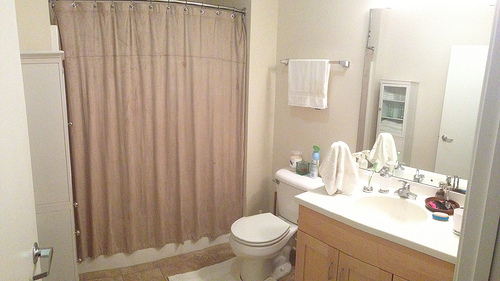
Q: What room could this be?
A: It is a bathroom.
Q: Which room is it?
A: It is a bathroom.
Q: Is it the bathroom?
A: Yes, it is the bathroom.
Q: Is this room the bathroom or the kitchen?
A: It is the bathroom.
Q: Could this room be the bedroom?
A: No, it is the bathroom.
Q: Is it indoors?
A: Yes, it is indoors.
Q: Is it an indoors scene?
A: Yes, it is indoors.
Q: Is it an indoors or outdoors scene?
A: It is indoors.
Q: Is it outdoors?
A: No, it is indoors.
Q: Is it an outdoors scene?
A: No, it is indoors.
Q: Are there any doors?
A: Yes, there is a door.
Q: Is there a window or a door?
A: Yes, there is a door.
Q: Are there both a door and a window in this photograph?
A: No, there is a door but no windows.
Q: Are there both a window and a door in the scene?
A: No, there is a door but no windows.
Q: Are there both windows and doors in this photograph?
A: No, there is a door but no windows.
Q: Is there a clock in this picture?
A: No, there are no clocks.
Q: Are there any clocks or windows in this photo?
A: No, there are no clocks or windows.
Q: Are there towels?
A: Yes, there is a towel.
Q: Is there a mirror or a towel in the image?
A: Yes, there is a towel.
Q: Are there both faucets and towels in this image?
A: Yes, there are both a towel and a faucet.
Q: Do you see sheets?
A: No, there are no sheets.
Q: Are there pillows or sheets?
A: No, there are no sheets or pillows.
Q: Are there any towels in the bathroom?
A: Yes, there is a towel in the bathroom.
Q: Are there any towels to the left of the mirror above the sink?
A: Yes, there is a towel to the left of the mirror.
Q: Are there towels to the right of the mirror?
A: No, the towel is to the left of the mirror.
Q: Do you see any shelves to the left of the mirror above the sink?
A: No, there is a towel to the left of the mirror.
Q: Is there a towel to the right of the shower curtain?
A: Yes, there is a towel to the right of the shower curtain.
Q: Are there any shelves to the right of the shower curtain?
A: No, there is a towel to the right of the shower curtain.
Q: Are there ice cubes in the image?
A: No, there are no ice cubes.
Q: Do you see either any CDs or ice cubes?
A: No, there are no ice cubes or cds.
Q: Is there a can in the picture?
A: Yes, there is a can.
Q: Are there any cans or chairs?
A: Yes, there is a can.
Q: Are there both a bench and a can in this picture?
A: No, there is a can but no benches.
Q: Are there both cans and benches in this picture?
A: No, there is a can but no benches.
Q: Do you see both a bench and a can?
A: No, there is a can but no benches.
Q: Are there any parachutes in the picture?
A: No, there are no parachutes.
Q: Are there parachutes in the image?
A: No, there are no parachutes.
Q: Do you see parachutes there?
A: No, there are no parachutes.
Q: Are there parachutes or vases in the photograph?
A: No, there are no parachutes or vases.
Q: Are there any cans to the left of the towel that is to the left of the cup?
A: Yes, there is a can to the left of the towel.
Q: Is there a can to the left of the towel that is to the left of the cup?
A: Yes, there is a can to the left of the towel.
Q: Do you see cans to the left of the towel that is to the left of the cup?
A: Yes, there is a can to the left of the towel.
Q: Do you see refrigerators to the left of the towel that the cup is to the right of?
A: No, there is a can to the left of the towel.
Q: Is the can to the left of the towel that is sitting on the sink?
A: Yes, the can is to the left of the towel.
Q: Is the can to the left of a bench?
A: No, the can is to the left of the towel.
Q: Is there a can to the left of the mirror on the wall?
A: Yes, there is a can to the left of the mirror.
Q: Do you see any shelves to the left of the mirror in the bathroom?
A: No, there is a can to the left of the mirror.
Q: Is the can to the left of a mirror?
A: Yes, the can is to the left of a mirror.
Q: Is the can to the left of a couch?
A: No, the can is to the left of a mirror.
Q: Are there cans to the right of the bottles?
A: Yes, there is a can to the right of the bottles.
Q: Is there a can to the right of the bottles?
A: Yes, there is a can to the right of the bottles.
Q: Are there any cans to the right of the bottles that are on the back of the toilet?
A: Yes, there is a can to the right of the bottles.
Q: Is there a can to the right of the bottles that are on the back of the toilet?
A: Yes, there is a can to the right of the bottles.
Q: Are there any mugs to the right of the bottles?
A: No, there is a can to the right of the bottles.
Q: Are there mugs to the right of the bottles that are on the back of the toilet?
A: No, there is a can to the right of the bottles.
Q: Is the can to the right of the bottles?
A: Yes, the can is to the right of the bottles.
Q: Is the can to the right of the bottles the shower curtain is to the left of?
A: Yes, the can is to the right of the bottles.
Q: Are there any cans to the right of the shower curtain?
A: Yes, there is a can to the right of the shower curtain.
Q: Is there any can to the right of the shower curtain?
A: Yes, there is a can to the right of the shower curtain.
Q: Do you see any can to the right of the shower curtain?
A: Yes, there is a can to the right of the shower curtain.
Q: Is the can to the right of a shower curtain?
A: Yes, the can is to the right of a shower curtain.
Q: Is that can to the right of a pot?
A: No, the can is to the right of a shower curtain.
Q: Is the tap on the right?
A: Yes, the tap is on the right of the image.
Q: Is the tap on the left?
A: No, the tap is on the right of the image.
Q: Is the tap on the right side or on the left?
A: The tap is on the right of the image.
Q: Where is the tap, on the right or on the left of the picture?
A: The tap is on the right of the image.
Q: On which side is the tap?
A: The tap is on the right of the image.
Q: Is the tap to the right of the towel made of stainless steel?
A: Yes, the tap is made of stainless steel.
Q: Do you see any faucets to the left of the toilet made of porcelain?
A: No, the faucet is to the right of the toilet.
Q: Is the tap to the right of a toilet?
A: Yes, the tap is to the right of a toilet.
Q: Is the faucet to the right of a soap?
A: No, the faucet is to the right of a toilet.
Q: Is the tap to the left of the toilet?
A: No, the tap is to the right of the toilet.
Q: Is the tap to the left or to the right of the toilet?
A: The tap is to the right of the toilet.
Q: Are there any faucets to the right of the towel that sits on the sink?
A: Yes, there is a faucet to the right of the towel.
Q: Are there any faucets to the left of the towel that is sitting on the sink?
A: No, the faucet is to the right of the towel.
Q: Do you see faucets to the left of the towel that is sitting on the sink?
A: No, the faucet is to the right of the towel.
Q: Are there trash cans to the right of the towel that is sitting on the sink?
A: No, there is a faucet to the right of the towel.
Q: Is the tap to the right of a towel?
A: Yes, the tap is to the right of a towel.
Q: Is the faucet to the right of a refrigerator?
A: No, the faucet is to the right of a towel.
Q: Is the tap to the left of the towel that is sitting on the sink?
A: No, the tap is to the right of the towel.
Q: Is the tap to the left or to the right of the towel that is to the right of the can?
A: The tap is to the right of the towel.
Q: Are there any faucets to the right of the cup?
A: Yes, there is a faucet to the right of the cup.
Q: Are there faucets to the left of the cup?
A: No, the faucet is to the right of the cup.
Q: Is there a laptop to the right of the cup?
A: No, there is a faucet to the right of the cup.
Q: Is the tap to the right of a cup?
A: Yes, the tap is to the right of a cup.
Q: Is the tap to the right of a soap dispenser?
A: No, the tap is to the right of a cup.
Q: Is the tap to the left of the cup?
A: No, the tap is to the right of the cup.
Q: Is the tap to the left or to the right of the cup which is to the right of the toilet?
A: The tap is to the right of the cup.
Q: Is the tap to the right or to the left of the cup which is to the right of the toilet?
A: The tap is to the right of the cup.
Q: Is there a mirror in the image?
A: Yes, there is a mirror.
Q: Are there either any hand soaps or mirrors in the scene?
A: Yes, there is a mirror.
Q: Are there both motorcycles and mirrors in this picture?
A: No, there is a mirror but no motorcycles.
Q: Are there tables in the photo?
A: No, there are no tables.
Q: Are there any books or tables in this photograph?
A: No, there are no tables or books.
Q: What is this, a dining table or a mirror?
A: This is a mirror.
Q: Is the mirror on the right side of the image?
A: Yes, the mirror is on the right of the image.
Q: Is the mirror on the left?
A: No, the mirror is on the right of the image.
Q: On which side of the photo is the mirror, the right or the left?
A: The mirror is on the right of the image.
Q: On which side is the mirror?
A: The mirror is on the right of the image.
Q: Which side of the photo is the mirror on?
A: The mirror is on the right of the image.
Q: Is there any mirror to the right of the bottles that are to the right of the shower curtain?
A: Yes, there is a mirror to the right of the bottles.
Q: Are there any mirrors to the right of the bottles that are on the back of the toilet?
A: Yes, there is a mirror to the right of the bottles.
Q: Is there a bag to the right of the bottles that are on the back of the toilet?
A: No, there is a mirror to the right of the bottles.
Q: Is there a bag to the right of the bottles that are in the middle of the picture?
A: No, there is a mirror to the right of the bottles.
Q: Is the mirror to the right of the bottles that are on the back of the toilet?
A: Yes, the mirror is to the right of the bottles.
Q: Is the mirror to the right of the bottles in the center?
A: Yes, the mirror is to the right of the bottles.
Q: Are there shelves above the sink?
A: No, there is a mirror above the sink.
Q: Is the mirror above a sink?
A: Yes, the mirror is above a sink.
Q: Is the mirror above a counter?
A: No, the mirror is above a sink.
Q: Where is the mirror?
A: The mirror is in the bathroom.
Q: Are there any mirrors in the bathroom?
A: Yes, there is a mirror in the bathroom.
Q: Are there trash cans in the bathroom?
A: No, there is a mirror in the bathroom.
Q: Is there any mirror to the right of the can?
A: Yes, there is a mirror to the right of the can.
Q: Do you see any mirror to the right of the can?
A: Yes, there is a mirror to the right of the can.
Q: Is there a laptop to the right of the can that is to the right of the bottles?
A: No, there is a mirror to the right of the can.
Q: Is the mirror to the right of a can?
A: Yes, the mirror is to the right of a can.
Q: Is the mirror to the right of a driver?
A: No, the mirror is to the right of a can.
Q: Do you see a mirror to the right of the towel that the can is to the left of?
A: Yes, there is a mirror to the right of the towel.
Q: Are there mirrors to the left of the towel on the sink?
A: No, the mirror is to the right of the towel.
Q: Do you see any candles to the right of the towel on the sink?
A: No, there is a mirror to the right of the towel.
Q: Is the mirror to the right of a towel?
A: Yes, the mirror is to the right of a towel.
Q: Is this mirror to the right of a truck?
A: No, the mirror is to the right of a towel.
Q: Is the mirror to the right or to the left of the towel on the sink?
A: The mirror is to the right of the towel.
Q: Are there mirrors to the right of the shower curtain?
A: Yes, there is a mirror to the right of the shower curtain.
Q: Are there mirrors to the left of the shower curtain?
A: No, the mirror is to the right of the shower curtain.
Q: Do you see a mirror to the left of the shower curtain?
A: No, the mirror is to the right of the shower curtain.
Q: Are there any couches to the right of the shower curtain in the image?
A: No, there is a mirror to the right of the shower curtain.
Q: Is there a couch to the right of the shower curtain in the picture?
A: No, there is a mirror to the right of the shower curtain.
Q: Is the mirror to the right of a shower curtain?
A: Yes, the mirror is to the right of a shower curtain.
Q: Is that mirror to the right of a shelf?
A: No, the mirror is to the right of a shower curtain.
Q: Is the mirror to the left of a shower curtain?
A: No, the mirror is to the right of a shower curtain.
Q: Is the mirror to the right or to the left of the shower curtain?
A: The mirror is to the right of the shower curtain.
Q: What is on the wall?
A: The mirror is on the wall.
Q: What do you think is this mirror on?
A: The mirror is on the wall.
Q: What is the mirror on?
A: The mirror is on the wall.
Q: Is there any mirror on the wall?
A: Yes, there is a mirror on the wall.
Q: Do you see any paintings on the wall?
A: No, there is a mirror on the wall.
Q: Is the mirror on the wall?
A: Yes, the mirror is on the wall.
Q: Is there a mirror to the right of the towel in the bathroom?
A: Yes, there is a mirror to the right of the towel.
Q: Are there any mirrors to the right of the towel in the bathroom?
A: Yes, there is a mirror to the right of the towel.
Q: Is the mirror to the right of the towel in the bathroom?
A: Yes, the mirror is to the right of the towel.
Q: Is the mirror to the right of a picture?
A: No, the mirror is to the right of the towel.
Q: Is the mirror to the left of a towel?
A: No, the mirror is to the right of a towel.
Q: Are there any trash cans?
A: No, there are no trash cans.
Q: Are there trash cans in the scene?
A: No, there are no trash cans.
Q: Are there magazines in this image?
A: No, there are no magazines.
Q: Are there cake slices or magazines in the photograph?
A: No, there are no magazines or cake slices.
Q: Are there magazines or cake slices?
A: No, there are no magazines or cake slices.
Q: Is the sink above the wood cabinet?
A: Yes, the sink is above the cabinet.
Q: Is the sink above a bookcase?
A: No, the sink is above the cabinet.